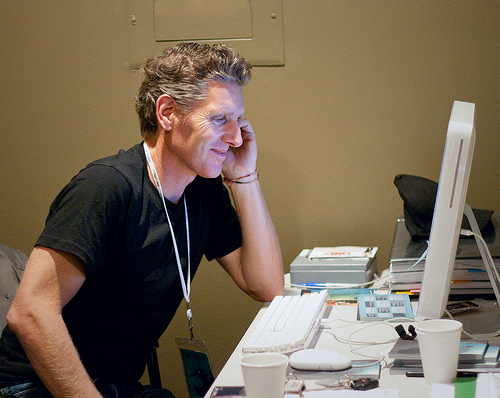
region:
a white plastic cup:
[401, 314, 478, 397]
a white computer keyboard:
[249, 278, 336, 358]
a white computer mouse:
[277, 342, 371, 379]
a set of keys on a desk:
[321, 377, 389, 395]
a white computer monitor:
[400, 90, 480, 338]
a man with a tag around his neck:
[176, 139, 220, 396]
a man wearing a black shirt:
[85, 46, 247, 278]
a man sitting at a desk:
[158, 64, 390, 394]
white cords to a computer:
[315, 313, 400, 370]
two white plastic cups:
[416, 306, 468, 383]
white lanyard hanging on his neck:
[143, 138, 212, 396]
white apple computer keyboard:
[242, 285, 332, 355]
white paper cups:
[411, 315, 461, 384]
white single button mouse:
[288, 340, 354, 375]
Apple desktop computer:
[410, 90, 480, 331]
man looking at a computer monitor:
[9, 36, 298, 393]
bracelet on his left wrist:
[222, 170, 267, 196]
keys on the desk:
[316, 368, 381, 396]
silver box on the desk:
[287, 239, 379, 286]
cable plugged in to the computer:
[460, 224, 499, 287]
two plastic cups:
[396, 312, 476, 387]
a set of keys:
[334, 363, 392, 397]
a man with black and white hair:
[138, 37, 250, 137]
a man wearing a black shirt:
[59, 129, 221, 325]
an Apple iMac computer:
[417, 99, 498, 339]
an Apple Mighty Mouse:
[286, 348, 351, 373]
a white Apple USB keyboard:
[241, 289, 333, 355]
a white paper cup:
[413, 316, 461, 384]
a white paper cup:
[237, 349, 287, 397]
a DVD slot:
[446, 138, 466, 208]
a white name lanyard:
[140, 137, 214, 397]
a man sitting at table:
[3, 42, 285, 397]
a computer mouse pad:
[287, 359, 380, 379]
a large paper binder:
[389, 217, 496, 294]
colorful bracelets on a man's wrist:
[221, 166, 261, 186]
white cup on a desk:
[236, 350, 291, 397]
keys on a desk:
[302, 373, 380, 396]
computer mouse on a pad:
[288, 346, 358, 371]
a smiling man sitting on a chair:
[0, 38, 285, 395]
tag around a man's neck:
[137, 140, 217, 397]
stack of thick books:
[291, 243, 381, 285]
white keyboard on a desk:
[240, 287, 330, 354]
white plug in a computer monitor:
[460, 229, 499, 287]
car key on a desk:
[349, 374, 382, 390]